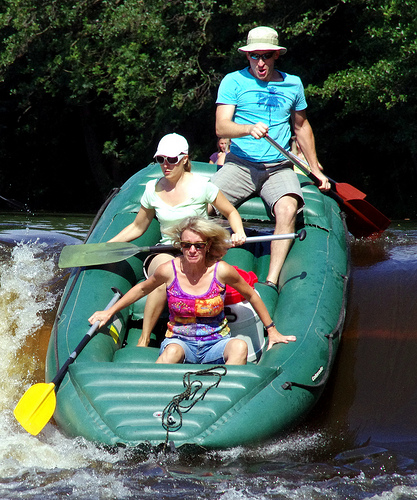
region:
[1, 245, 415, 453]
a very small river waterfall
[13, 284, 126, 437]
a black gray and yellow paddle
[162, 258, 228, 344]
a floral tie dye tank top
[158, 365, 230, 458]
a black string attached to a green raft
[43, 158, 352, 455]
an inflatable green life raft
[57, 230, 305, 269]
a green black and gray paddle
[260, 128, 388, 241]
a red gray and black oar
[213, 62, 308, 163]
a blue shirt with a palm tree graffic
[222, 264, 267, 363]
a white and red water canister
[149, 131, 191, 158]
a white baseball cap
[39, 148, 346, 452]
a dark green raft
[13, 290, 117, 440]
a yellow and black oar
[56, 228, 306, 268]
a green and black oar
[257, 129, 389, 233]
a red and silver oar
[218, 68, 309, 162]
a light blue t-shirt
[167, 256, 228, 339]
a multi colored blouse top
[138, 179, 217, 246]
a light green blouse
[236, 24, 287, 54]
a light brown brimmed hat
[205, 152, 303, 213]
a pair of men's shorts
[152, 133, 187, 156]
a lady's white hat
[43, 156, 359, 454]
occupied green raft in a moving river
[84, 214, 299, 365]
middle-aged woman in a raft moving through a river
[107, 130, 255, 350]
young woman riding a raft in a river holding a paddle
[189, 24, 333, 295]
man wearing a blue shirt rafting with a paddle in his hand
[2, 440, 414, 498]
murky moving water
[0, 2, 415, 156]
trees at the side of a river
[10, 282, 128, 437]
yellow raft paddle being held by a middle-aged woman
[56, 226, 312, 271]
dirty green raft paddle being held by a woman on a raft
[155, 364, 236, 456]
black rope attached to a green raft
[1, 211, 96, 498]
murky moving water in a river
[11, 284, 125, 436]
yellow, black and silver oar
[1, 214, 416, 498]
brown rough water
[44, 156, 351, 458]
green inflated boat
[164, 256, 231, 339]
bright multi-colored tank top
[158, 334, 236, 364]
blue jeans shorts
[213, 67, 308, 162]
mans bright blue shirt decorated with a palm tree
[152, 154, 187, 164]
woman's white rimmed sunglasses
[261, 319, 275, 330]
woman's black wrist watch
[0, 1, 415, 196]
green tree over hang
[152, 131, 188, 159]
woman's white baseball hat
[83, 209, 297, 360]
woman steadies herself starting down rapids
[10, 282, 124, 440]
yellow, black and gray rowing oar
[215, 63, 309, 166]
light blue shirt with a dark blue palm tree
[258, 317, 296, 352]
woman's wrist with a watch on it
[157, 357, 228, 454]
rope on the front end of a boat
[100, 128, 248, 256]
woman with a white shirt and hat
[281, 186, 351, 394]
rope on the side of an inflatable boat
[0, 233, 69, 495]
rapids in the water with yellow oar paddle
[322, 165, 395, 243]
two red oar paddle ends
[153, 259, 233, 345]
purple pink and yellow woman's shirt